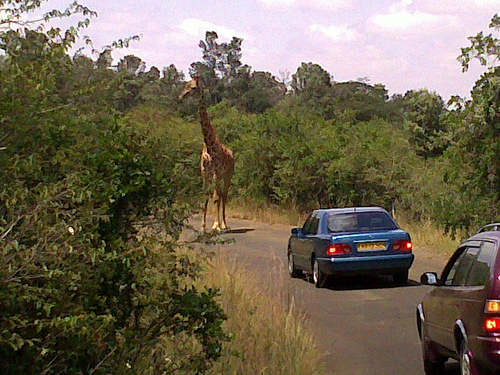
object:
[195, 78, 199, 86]
ear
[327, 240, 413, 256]
tail lights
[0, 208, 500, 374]
land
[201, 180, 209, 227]
giraffe leg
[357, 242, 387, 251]
plate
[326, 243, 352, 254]
brake light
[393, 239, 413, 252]
brake light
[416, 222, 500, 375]
car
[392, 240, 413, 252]
light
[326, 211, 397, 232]
window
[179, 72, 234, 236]
giraffe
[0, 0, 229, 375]
trees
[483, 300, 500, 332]
tail light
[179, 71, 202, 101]
head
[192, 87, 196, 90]
eye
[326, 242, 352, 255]
lights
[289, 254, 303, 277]
tire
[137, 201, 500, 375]
road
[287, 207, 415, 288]
car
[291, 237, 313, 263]
door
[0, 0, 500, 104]
purple sky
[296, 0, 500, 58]
white clouds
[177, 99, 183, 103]
mouth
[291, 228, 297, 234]
mirror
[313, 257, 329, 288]
tire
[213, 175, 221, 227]
leg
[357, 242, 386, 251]
license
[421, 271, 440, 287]
mirror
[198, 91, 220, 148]
neck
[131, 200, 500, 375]
path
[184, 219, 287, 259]
asphalt